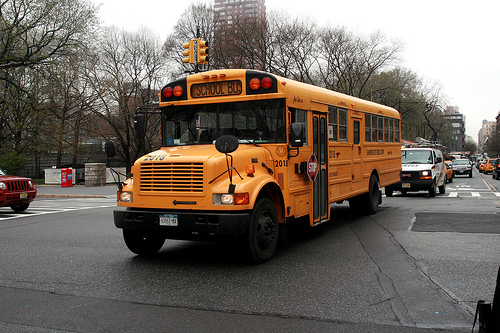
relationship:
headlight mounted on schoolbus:
[219, 192, 235, 205] [102, 68, 402, 265]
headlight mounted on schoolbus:
[118, 190, 132, 201] [102, 68, 402, 265]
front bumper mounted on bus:
[111, 207, 252, 236] [101, 67, 404, 260]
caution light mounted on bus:
[247, 74, 261, 91] [101, 67, 404, 260]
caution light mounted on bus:
[260, 75, 273, 89] [101, 67, 404, 260]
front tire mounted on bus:
[234, 196, 281, 265] [101, 67, 404, 260]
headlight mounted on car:
[421, 170, 430, 177] [383, 143, 446, 194]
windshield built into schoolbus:
[159, 96, 285, 145] [102, 68, 402, 265]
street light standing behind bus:
[180, 24, 211, 75] [101, 67, 404, 260]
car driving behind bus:
[384, 147, 445, 196] [101, 67, 404, 260]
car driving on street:
[439, 160, 454, 182] [2, 161, 484, 331]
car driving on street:
[451, 154, 472, 180] [2, 161, 484, 331]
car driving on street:
[384, 147, 445, 196] [2, 161, 484, 331]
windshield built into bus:
[159, 96, 285, 145] [101, 67, 404, 260]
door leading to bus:
[311, 110, 330, 221] [101, 67, 404, 260]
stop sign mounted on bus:
[304, 153, 318, 182] [101, 67, 404, 260]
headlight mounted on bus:
[219, 192, 235, 205] [101, 67, 404, 260]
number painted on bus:
[273, 157, 291, 167] [101, 67, 404, 260]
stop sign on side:
[304, 153, 318, 182] [280, 72, 401, 232]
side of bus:
[280, 72, 401, 232] [101, 67, 404, 260]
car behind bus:
[384, 147, 445, 196] [101, 67, 404, 260]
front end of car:
[0, 168, 37, 216] [0, 158, 33, 212]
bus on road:
[105, 67, 404, 261] [12, 165, 483, 324]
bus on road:
[105, 67, 404, 261] [5, 179, 431, 330]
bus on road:
[105, 67, 404, 261] [14, 185, 484, 303]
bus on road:
[105, 67, 404, 261] [7, 188, 485, 330]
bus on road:
[105, 67, 404, 261] [6, 176, 485, 310]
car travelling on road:
[402, 145, 445, 196] [7, 188, 485, 330]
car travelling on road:
[439, 160, 454, 182] [7, 188, 485, 330]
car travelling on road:
[451, 153, 472, 180] [7, 188, 485, 330]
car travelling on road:
[0, 158, 33, 224] [7, 188, 485, 330]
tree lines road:
[4, 1, 68, 183] [12, 165, 483, 324]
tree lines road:
[40, 27, 87, 173] [12, 165, 483, 324]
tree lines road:
[83, 34, 153, 177] [12, 165, 483, 324]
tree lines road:
[132, 33, 157, 162] [12, 165, 483, 324]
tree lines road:
[163, 3, 240, 72] [12, 165, 483, 324]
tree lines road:
[231, 14, 293, 78] [12, 165, 483, 324]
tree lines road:
[260, 8, 314, 74] [12, 165, 483, 324]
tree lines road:
[320, 34, 399, 99] [12, 165, 483, 324]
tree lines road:
[376, 67, 416, 142] [12, 165, 483, 324]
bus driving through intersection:
[105, 67, 404, 261] [47, 177, 484, 316]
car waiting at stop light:
[0, 158, 33, 212] [174, 29, 215, 69]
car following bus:
[384, 147, 445, 196] [105, 67, 404, 261]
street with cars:
[12, 65, 482, 327] [11, 92, 485, 251]